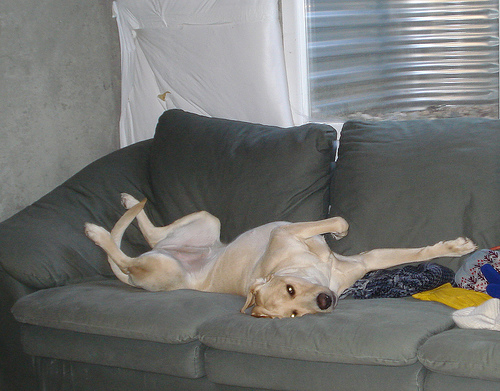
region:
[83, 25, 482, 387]
dog laying on couch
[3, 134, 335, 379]
tan dog on couch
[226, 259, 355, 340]
head of dog laying down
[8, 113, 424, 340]
dog laying on its back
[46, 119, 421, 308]
stretched out dog on couch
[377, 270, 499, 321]
black and yellow objects on couch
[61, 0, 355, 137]
white sheet behind couch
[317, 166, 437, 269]
legs of dog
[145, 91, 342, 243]
grey couch pillow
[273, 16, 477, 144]
blinds behind couch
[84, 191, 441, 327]
white dog on couch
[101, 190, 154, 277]
curled tail between legs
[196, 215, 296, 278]
dog belly pointing up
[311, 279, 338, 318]
nose on dog face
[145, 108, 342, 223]
blue cushion on couch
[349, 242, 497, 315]
clothing on blue couch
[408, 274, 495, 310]
yellow glove on couch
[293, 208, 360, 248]
bent paw on dog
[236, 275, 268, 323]
ear on dog's head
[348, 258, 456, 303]
blue blanket with fringe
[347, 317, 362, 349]
the couch is gray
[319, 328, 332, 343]
the couch is gray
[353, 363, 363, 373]
the couch is gray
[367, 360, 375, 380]
the couch is gray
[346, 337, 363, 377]
the couch is gray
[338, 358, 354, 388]
the couch is gray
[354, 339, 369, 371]
the couch is gray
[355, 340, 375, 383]
the couch is gray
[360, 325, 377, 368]
the couch is gray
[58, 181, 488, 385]
white dog laying on gray couch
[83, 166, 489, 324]
white dog with stomach exposed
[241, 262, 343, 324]
white dog with eyes reflecting light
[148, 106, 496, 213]
two gray couch pillows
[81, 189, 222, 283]
two back dog legs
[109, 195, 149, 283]
one white dog tail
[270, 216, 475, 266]
two front dog legs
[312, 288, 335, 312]
one black dog nose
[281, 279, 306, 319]
two dark dog eyes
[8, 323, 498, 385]
front edge of three couch cushions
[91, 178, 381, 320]
White Dog on the Couch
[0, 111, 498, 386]
A Comfy Grey Couch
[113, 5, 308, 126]
Some White Plastic Sheeting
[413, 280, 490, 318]
A Yellow object on the couch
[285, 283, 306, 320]
Dog's two glaring eyeballs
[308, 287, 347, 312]
Dog's Dark black nose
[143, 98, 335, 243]
Dark Grey Couch Cusion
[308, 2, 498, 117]
A Blurry Glass window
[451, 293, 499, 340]
A white object on the couch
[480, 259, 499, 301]
A Blue object on the couch